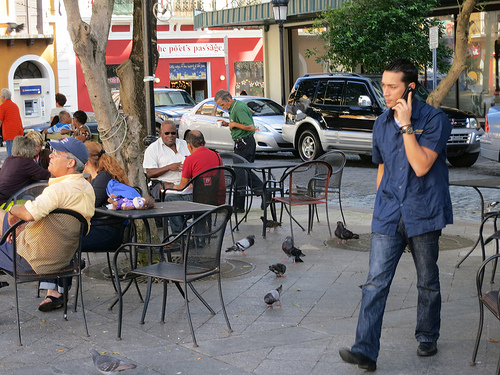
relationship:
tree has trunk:
[61, 0, 161, 283] [97, 120, 164, 282]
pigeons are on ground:
[223, 217, 365, 320] [253, 303, 362, 373]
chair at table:
[258, 153, 338, 253] [223, 152, 310, 243]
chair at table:
[284, 145, 351, 235] [223, 152, 310, 243]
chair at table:
[213, 146, 278, 229] [223, 152, 310, 243]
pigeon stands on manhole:
[331, 217, 361, 243] [322, 222, 478, 254]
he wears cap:
[0, 133, 98, 314] [46, 128, 89, 156]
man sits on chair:
[165, 130, 222, 247] [185, 165, 237, 245]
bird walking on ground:
[228, 229, 253, 261] [0, 196, 499, 374]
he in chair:
[0, 133, 98, 314] [1, 207, 95, 348]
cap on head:
[46, 130, 90, 164] [45, 148, 85, 174]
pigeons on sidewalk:
[248, 231, 323, 311] [218, 200, 377, 367]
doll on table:
[104, 186, 158, 214] [89, 191, 231, 328]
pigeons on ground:
[213, 192, 357, 301] [0, 196, 499, 374]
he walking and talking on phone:
[337, 57, 457, 371] [390, 87, 414, 124]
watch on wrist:
[399, 130, 424, 145] [384, 95, 419, 135]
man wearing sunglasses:
[142, 121, 193, 198] [141, 109, 188, 150]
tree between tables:
[61, 0, 161, 283] [94, 185, 239, 327]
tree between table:
[61, 0, 161, 283] [119, 184, 171, 192]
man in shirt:
[165, 130, 222, 247] [181, 146, 232, 194]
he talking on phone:
[337, 57, 457, 371] [396, 83, 416, 107]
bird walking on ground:
[262, 284, 286, 309] [0, 196, 499, 374]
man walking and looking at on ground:
[212, 87, 277, 216] [0, 140, 499, 373]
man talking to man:
[142, 121, 193, 198] [165, 130, 222, 247]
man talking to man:
[165, 130, 222, 247] [142, 121, 193, 198]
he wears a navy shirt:
[337, 57, 457, 371] [369, 100, 454, 238]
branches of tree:
[352, 33, 455, 68] [306, 3, 461, 95]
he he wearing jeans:
[337, 57, 457, 368] [357, 223, 444, 338]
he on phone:
[337, 57, 457, 371] [397, 86, 414, 107]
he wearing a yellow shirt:
[4, 134, 94, 274] [22, 173, 98, 245]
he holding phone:
[337, 57, 457, 371] [390, 89, 413, 115]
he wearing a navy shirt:
[337, 57, 457, 371] [365, 114, 456, 236]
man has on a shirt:
[165, 130, 222, 247] [178, 143, 229, 205]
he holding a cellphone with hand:
[337, 57, 457, 371] [399, 79, 421, 104]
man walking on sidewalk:
[212, 87, 272, 213] [225, 210, 269, 222]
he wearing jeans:
[337, 57, 457, 371] [354, 216, 440, 359]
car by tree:
[278, 72, 485, 172] [314, 2, 439, 90]